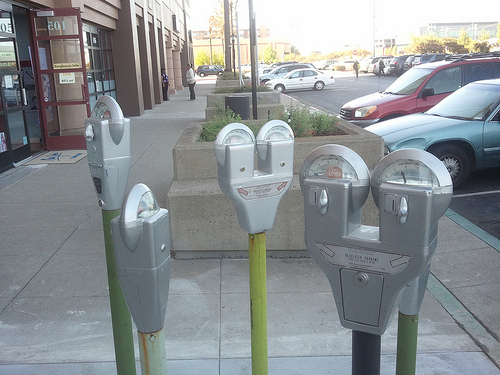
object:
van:
[334, 55, 499, 130]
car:
[362, 78, 499, 190]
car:
[263, 68, 336, 92]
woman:
[182, 59, 200, 103]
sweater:
[183, 67, 199, 87]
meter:
[212, 117, 298, 237]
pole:
[244, 231, 273, 374]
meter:
[298, 141, 456, 338]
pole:
[348, 328, 384, 374]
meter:
[108, 179, 174, 375]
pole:
[136, 325, 171, 374]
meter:
[81, 92, 136, 215]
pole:
[100, 205, 139, 374]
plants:
[200, 101, 343, 141]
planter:
[213, 112, 295, 375]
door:
[0, 5, 93, 169]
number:
[45, 17, 68, 35]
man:
[353, 58, 363, 77]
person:
[375, 58, 388, 81]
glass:
[32, 15, 91, 141]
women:
[157, 62, 170, 102]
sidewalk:
[2, 69, 497, 372]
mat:
[15, 150, 91, 165]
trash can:
[221, 92, 254, 125]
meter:
[394, 256, 434, 317]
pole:
[394, 310, 422, 374]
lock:
[353, 271, 369, 287]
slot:
[307, 185, 322, 206]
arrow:
[399, 168, 409, 184]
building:
[0, 1, 196, 175]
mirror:
[420, 87, 435, 97]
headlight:
[351, 102, 380, 121]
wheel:
[427, 139, 475, 193]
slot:
[383, 191, 400, 216]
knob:
[315, 186, 331, 217]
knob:
[394, 192, 410, 225]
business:
[0, 1, 122, 180]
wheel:
[310, 79, 326, 91]